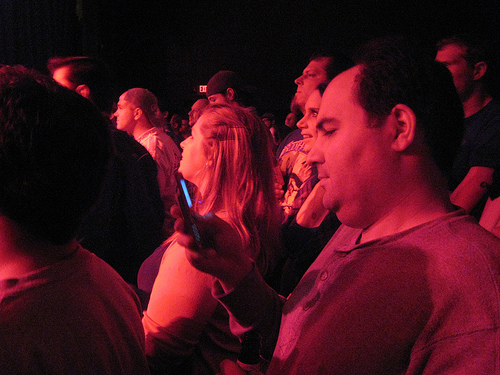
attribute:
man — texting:
[174, 47, 499, 374]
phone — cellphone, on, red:
[174, 173, 206, 247]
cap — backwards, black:
[204, 68, 253, 94]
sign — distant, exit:
[197, 84, 207, 92]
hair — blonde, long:
[197, 104, 281, 259]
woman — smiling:
[286, 77, 353, 250]